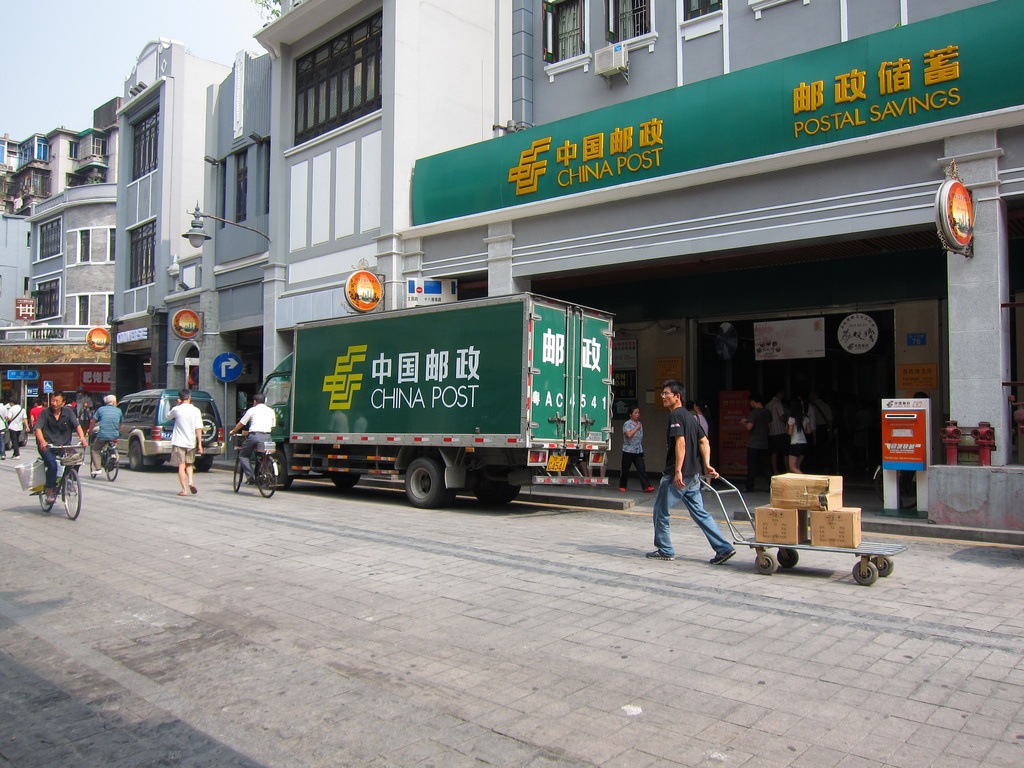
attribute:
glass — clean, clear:
[119, 223, 156, 284]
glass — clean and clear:
[613, 276, 890, 393]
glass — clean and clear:
[693, 320, 756, 398]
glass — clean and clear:
[764, 359, 847, 466]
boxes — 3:
[744, 467, 866, 547]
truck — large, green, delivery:
[247, 290, 623, 511]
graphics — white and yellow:
[312, 322, 492, 429]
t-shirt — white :
[161, 402, 205, 450]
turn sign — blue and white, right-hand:
[213, 346, 242, 383]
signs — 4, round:
[0, 175, 983, 361]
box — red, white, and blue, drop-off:
[878, 390, 939, 477]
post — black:
[893, 474, 926, 518]